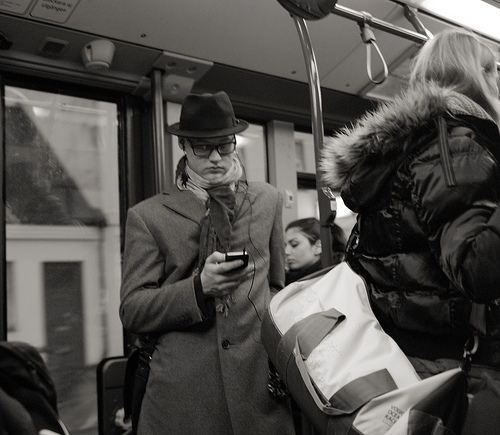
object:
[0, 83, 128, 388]
house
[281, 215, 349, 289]
woman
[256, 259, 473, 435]
bag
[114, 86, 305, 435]
man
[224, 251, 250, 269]
cellphone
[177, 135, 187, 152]
ear buds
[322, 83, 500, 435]
coat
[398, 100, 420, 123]
fur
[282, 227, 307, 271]
face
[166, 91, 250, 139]
hat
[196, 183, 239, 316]
scarf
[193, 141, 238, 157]
eyeglasses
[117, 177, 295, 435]
coat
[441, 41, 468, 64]
hair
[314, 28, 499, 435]
people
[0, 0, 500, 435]
train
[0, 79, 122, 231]
window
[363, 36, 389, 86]
ring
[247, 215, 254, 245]
wire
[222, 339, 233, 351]
button